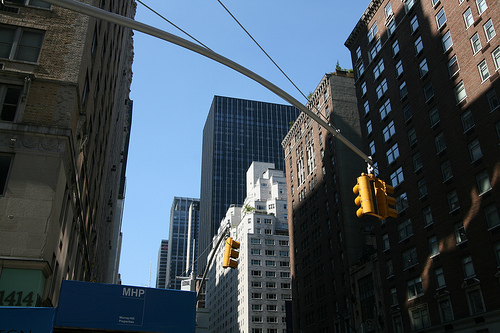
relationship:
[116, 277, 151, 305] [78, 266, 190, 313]
"mhp" written on box written on box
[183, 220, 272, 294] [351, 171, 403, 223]
lights on traffic a traffic light stoplight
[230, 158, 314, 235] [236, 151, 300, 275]
top of building a white building white building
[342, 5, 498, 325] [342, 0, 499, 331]
windows on building has windows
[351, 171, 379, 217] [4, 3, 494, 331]
stoplight in picture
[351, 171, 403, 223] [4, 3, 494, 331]
stoplight in picture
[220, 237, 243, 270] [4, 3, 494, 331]
lights on traffic in picture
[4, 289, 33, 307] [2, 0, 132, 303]
number on building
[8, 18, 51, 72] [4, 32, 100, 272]
window on building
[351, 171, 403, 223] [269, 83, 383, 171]
stoplight hanging on pole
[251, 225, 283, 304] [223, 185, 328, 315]
windows on building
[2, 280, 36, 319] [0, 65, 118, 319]
numbers on building